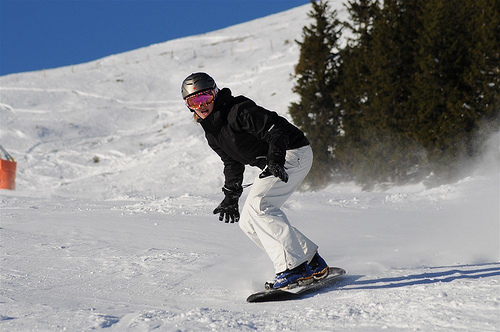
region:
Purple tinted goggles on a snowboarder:
[179, 87, 219, 112]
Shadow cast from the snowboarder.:
[321, 262, 499, 289]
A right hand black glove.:
[213, 187, 242, 224]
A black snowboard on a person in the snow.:
[246, 265, 347, 303]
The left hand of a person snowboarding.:
[258, 160, 291, 182]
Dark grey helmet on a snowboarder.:
[181, 72, 218, 101]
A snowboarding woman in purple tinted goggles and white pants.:
[182, 69, 329, 289]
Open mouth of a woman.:
[197, 107, 211, 117]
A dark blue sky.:
[1, 2, 310, 77]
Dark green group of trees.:
[288, 2, 499, 195]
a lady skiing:
[177, 72, 346, 304]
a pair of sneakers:
[259, 252, 327, 289]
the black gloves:
[211, 148, 290, 223]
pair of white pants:
[236, 141, 316, 273]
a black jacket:
[195, 88, 311, 193]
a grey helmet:
[178, 70, 218, 97]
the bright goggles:
[183, 91, 219, 112]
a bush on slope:
[284, 3, 496, 161]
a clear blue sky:
[0, 0, 315, 73]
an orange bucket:
[0, 144, 17, 189]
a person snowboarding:
[171, 66, 348, 301]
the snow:
[66, 202, 199, 304]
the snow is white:
[60, 206, 192, 301]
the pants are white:
[251, 192, 288, 250]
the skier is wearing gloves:
[215, 197, 240, 224]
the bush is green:
[331, 57, 448, 137]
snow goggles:
[184, 97, 209, 107]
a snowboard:
[247, 289, 292, 299]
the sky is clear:
[56, 9, 105, 46]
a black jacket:
[211, 120, 259, 155]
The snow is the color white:
[15, 211, 164, 316]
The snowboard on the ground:
[246, 258, 351, 303]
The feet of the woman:
[261, 247, 330, 290]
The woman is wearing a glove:
[211, 185, 244, 230]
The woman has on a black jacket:
[198, 85, 314, 200]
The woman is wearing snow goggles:
[176, 85, 226, 112]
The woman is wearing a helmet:
[173, 68, 221, 102]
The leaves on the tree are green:
[341, 19, 476, 146]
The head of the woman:
[171, 71, 221, 119]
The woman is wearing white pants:
[227, 142, 339, 275]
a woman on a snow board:
[180, 72, 352, 302]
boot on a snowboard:
[264, 262, 312, 290]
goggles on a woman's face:
[182, 87, 213, 107]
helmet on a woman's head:
[180, 71, 215, 96]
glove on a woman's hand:
[214, 180, 244, 220]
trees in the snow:
[290, 2, 498, 192]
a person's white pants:
[236, 149, 349, 271]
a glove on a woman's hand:
[257, 161, 288, 182]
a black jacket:
[188, 89, 310, 180]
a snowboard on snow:
[247, 267, 348, 302]